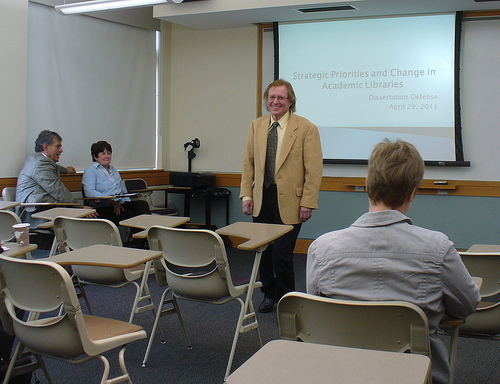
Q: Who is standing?
A: A man.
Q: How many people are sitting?
A: Three.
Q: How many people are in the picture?
A: Four.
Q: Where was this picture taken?
A: A classroom.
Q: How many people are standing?
A: One.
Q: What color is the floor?
A: Blue.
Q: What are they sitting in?
A: Desk chairs.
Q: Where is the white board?
A: Behind the standing man.